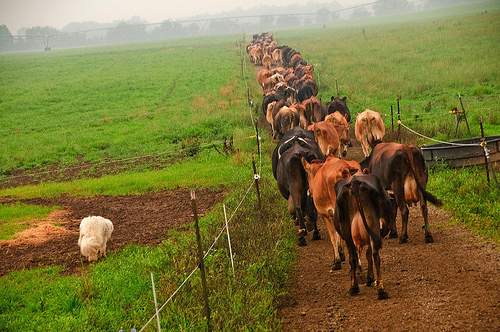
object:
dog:
[78, 216, 114, 262]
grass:
[0, 243, 139, 332]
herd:
[245, 33, 443, 300]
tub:
[420, 136, 500, 173]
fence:
[137, 33, 261, 332]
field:
[0, 0, 260, 332]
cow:
[266, 101, 279, 138]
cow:
[301, 157, 361, 270]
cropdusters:
[0, 0, 393, 52]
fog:
[0, 0, 499, 54]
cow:
[334, 174, 395, 300]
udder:
[351, 209, 373, 251]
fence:
[313, 72, 499, 188]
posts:
[420, 135, 500, 172]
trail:
[245, 32, 444, 299]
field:
[0, 0, 500, 332]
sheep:
[254, 174, 261, 179]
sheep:
[253, 173, 261, 180]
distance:
[0, 0, 500, 33]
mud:
[0, 153, 238, 299]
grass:
[0, 0, 500, 332]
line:
[245, 32, 443, 299]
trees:
[0, 25, 14, 53]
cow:
[359, 137, 444, 243]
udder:
[404, 170, 418, 207]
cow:
[276, 126, 326, 246]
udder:
[288, 193, 296, 216]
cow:
[355, 109, 386, 158]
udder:
[367, 132, 383, 149]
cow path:
[245, 0, 500, 332]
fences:
[478, 115, 490, 183]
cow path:
[279, 180, 499, 332]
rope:
[400, 123, 479, 146]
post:
[188, 190, 214, 332]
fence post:
[189, 190, 214, 332]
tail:
[350, 184, 383, 248]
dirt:
[137, 176, 298, 332]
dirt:
[370, 142, 420, 173]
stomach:
[312, 177, 336, 217]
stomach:
[379, 183, 394, 238]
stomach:
[277, 159, 289, 200]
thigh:
[335, 191, 360, 258]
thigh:
[365, 212, 380, 254]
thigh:
[417, 161, 428, 206]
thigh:
[384, 159, 406, 208]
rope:
[313, 71, 398, 120]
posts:
[448, 93, 471, 138]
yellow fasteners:
[397, 119, 487, 146]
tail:
[332, 117, 339, 126]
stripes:
[278, 136, 296, 160]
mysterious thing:
[89, 261, 96, 268]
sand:
[0, 210, 79, 248]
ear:
[86, 237, 104, 256]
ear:
[301, 157, 312, 174]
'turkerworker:
[401, 270, 408, 272]